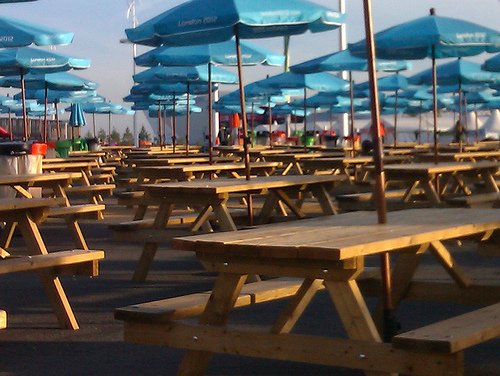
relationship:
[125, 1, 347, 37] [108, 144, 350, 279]
umbrella above table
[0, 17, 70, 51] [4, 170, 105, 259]
umbrella above table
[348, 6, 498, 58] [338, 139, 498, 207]
umbrella above table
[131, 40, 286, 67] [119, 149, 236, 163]
umbrella above table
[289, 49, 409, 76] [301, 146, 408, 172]
umbrella above table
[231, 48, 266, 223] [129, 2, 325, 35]
pole of umbrella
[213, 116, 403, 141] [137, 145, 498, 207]
people behind benches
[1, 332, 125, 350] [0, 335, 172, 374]
edge of shade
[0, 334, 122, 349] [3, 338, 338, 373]
edge of shade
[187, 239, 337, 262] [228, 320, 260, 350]
edge of a wood